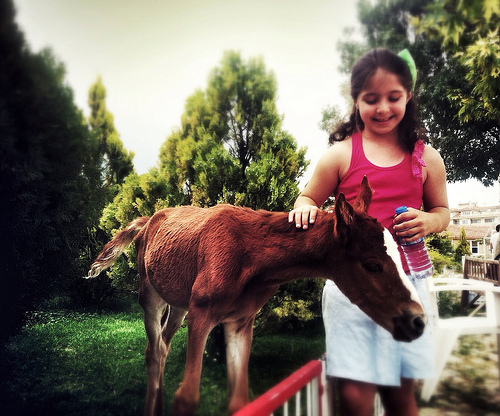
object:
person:
[486, 224, 500, 264]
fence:
[225, 351, 335, 416]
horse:
[80, 173, 428, 414]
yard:
[2, 265, 500, 414]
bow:
[396, 45, 418, 93]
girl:
[287, 43, 456, 416]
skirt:
[319, 267, 444, 391]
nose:
[405, 309, 430, 332]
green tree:
[316, 0, 500, 192]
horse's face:
[332, 207, 431, 345]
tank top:
[334, 130, 440, 282]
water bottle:
[393, 204, 437, 282]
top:
[333, 126, 441, 278]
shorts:
[321, 273, 449, 390]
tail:
[80, 214, 149, 284]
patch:
[380, 224, 425, 310]